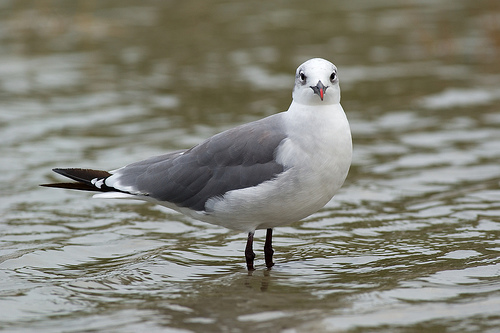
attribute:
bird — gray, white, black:
[37, 56, 354, 271]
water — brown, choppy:
[1, 0, 499, 333]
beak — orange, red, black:
[319, 87, 324, 101]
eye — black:
[299, 72, 306, 82]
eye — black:
[330, 72, 335, 80]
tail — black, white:
[38, 167, 114, 193]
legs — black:
[244, 227, 275, 272]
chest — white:
[283, 105, 351, 230]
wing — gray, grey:
[117, 121, 276, 199]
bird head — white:
[296, 57, 339, 89]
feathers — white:
[96, 167, 142, 196]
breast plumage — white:
[205, 104, 352, 234]